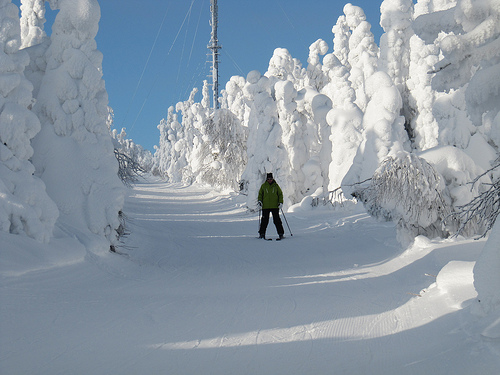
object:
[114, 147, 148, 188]
branch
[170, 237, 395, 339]
shadows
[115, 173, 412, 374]
path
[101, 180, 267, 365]
slope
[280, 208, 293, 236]
poles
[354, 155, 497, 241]
branches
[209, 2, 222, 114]
pole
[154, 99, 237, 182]
trees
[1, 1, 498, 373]
snow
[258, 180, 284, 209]
coat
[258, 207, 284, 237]
pants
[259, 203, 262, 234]
ski pole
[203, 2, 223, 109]
ice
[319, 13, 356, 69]
tree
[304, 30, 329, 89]
tree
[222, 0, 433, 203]
sunlight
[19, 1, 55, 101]
tree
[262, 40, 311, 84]
tree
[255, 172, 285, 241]
guy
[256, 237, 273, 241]
ski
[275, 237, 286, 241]
ski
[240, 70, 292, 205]
tree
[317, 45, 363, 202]
tree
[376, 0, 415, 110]
tree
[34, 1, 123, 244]
tree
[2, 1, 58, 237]
tree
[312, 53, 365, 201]
tree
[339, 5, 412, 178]
tree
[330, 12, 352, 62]
tree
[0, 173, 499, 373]
trail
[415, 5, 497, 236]
tree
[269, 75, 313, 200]
tree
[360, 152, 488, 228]
trees